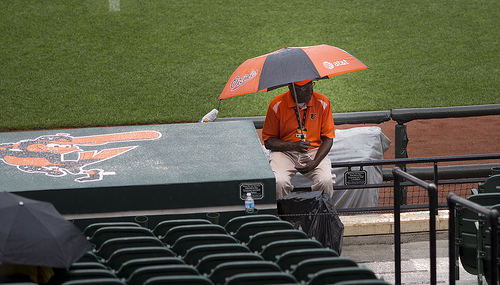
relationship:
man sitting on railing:
[262, 79, 336, 201] [218, 105, 499, 188]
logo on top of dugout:
[0, 129, 164, 183] [0, 117, 268, 208]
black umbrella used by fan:
[1, 190, 93, 270] [0, 262, 54, 283]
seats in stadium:
[83, 210, 382, 283] [15, 17, 499, 280]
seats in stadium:
[452, 174, 498, 281] [15, 17, 499, 280]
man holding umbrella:
[262, 79, 336, 201] [226, 42, 358, 89]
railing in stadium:
[389, 167, 497, 277] [1, 162, 498, 277]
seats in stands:
[61, 212, 388, 283] [8, 180, 482, 279]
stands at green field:
[8, 180, 482, 279] [0, 0, 500, 131]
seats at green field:
[61, 212, 388, 283] [0, 0, 500, 131]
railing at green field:
[213, 102, 500, 210] [0, 0, 500, 131]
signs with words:
[343, 168, 370, 188] [346, 170, 363, 177]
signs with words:
[343, 168, 370, 188] [348, 177, 365, 184]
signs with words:
[343, 168, 370, 188] [239, 187, 264, 194]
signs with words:
[343, 168, 370, 188] [247, 183, 264, 190]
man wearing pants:
[262, 79, 336, 201] [265, 146, 335, 198]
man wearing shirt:
[262, 79, 336, 201] [259, 90, 336, 142]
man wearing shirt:
[262, 79, 336, 201] [259, 90, 342, 152]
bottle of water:
[242, 191, 256, 213] [244, 190, 256, 213]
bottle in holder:
[242, 191, 256, 213] [240, 207, 257, 216]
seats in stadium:
[223, 207, 391, 281] [15, 17, 499, 280]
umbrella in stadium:
[217, 42, 369, 99] [15, 17, 499, 280]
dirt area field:
[243, 112, 498, 213] [1, 1, 498, 211]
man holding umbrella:
[262, 79, 336, 201] [217, 42, 369, 99]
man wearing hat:
[262, 79, 336, 201] [290, 75, 316, 87]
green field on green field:
[0, 0, 500, 127] [0, 0, 500, 131]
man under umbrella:
[246, 75, 365, 202] [216, 35, 371, 100]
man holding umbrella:
[262, 79, 336, 201] [214, 28, 391, 113]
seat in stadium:
[229, 212, 282, 227] [15, 17, 499, 280]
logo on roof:
[2, 126, 134, 182] [1, 118, 276, 218]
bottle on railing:
[198, 105, 218, 122] [214, 94, 499, 214]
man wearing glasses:
[262, 79, 336, 201] [278, 78, 318, 99]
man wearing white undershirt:
[262, 79, 336, 201] [293, 102, 308, 108]